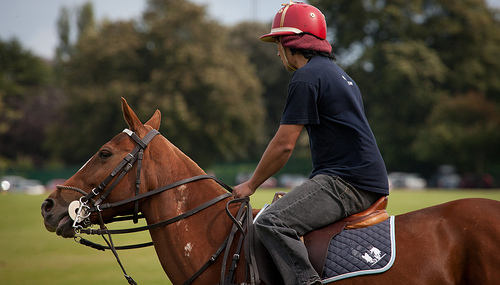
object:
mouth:
[46, 207, 82, 240]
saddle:
[268, 189, 405, 231]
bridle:
[52, 127, 161, 238]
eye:
[95, 146, 114, 162]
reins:
[92, 174, 248, 212]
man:
[230, 0, 390, 284]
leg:
[253, 172, 377, 284]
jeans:
[252, 170, 389, 284]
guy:
[231, 2, 389, 284]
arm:
[244, 69, 317, 188]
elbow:
[278, 142, 296, 156]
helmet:
[259, 2, 326, 43]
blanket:
[315, 215, 399, 219]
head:
[38, 95, 173, 239]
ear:
[117, 95, 143, 130]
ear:
[142, 108, 163, 134]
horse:
[40, 96, 500, 285]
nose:
[38, 197, 61, 216]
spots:
[181, 240, 199, 257]